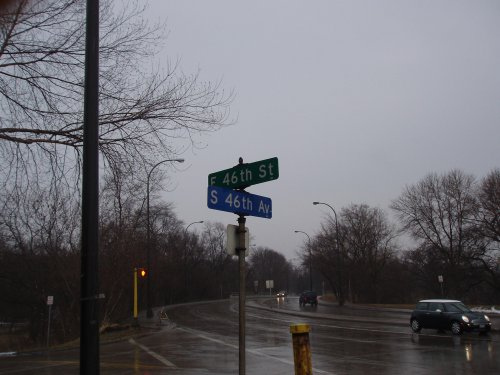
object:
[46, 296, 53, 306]
white sign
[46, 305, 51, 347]
pole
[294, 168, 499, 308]
trees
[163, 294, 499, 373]
road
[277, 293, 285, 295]
lights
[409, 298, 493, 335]
car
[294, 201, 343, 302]
posts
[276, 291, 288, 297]
car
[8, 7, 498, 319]
distance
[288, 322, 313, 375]
pole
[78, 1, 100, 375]
pole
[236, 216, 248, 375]
pole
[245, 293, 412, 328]
medium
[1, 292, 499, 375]
street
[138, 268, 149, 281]
lamp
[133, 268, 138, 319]
pole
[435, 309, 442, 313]
mirror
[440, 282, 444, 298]
post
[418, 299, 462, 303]
roof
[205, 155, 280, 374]
sign